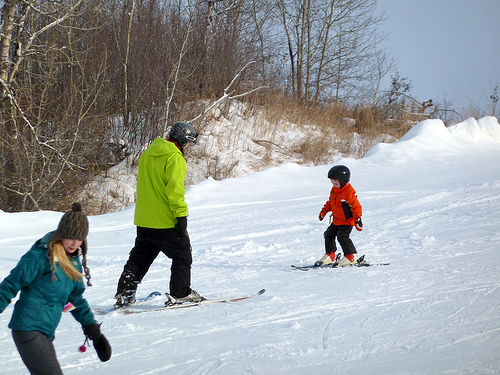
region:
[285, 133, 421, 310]
A boy on skiis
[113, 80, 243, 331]
a man on skiis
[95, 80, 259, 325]
a man with a green jacket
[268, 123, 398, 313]
a boy with a red jacket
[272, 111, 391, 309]
a boy with a black helmet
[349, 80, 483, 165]
a bank of snow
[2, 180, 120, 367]
a woman with a blue jacket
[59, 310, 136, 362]
mits being worn on hands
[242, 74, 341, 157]
dead grass in the bank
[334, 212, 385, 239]
a boy wearing mits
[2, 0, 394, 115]
a section of young trees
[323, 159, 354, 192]
toddlers black helmet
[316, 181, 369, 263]
orange and black cross country ski outfit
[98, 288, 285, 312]
adult cross country skis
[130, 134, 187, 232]
bright neon green parka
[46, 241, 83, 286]
a swatch on blonde hair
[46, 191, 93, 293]
a knitted hat topped with pom pom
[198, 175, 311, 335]
ski tracks in the snow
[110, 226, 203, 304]
black snow pants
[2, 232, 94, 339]
a teal colored girls parka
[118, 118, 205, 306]
man in green coat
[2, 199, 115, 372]
woman in blue coat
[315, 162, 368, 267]
child in orange coat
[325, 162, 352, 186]
child wearing black helmet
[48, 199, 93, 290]
woman wearing stocking cap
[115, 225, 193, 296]
man wearing black pants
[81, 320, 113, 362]
woman wearing black glove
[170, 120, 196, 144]
man wearing black helmet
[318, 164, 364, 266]
child skiing towards man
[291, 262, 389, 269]
child on black skis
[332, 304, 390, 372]
The snow is white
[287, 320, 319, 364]
The snow is white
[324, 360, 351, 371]
The snow is white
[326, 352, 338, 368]
The snow is white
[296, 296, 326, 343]
The snow is white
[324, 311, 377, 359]
The snow is white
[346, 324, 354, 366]
The snow is white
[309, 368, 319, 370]
The snow is white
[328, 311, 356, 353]
The snow is white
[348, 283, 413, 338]
The snow is white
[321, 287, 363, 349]
The snow is white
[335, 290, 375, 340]
The snow is white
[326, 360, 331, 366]
The snow is white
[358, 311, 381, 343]
The snow is white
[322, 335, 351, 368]
The snow is white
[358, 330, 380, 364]
The snow is white